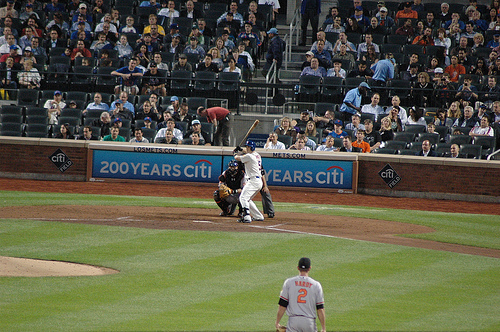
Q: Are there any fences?
A: No, there are no fences.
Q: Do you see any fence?
A: No, there are no fences.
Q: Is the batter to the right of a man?
A: No, the batter is to the left of a man.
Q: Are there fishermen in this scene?
A: No, there are no fishermen.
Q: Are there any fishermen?
A: No, there are no fishermen.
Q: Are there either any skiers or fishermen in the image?
A: No, there are no fishermen or skiers.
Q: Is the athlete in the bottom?
A: Yes, the athlete is in the bottom of the image.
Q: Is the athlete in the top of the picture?
A: No, the athlete is in the bottom of the image.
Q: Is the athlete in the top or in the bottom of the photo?
A: The athlete is in the bottom of the image.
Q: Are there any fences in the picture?
A: No, there are no fences.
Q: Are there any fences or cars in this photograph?
A: No, there are no fences or cars.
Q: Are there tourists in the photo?
A: No, there are no tourists.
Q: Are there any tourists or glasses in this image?
A: No, there are no tourists or glasses.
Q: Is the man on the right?
A: Yes, the man is on the right of the image.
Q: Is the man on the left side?
A: No, the man is on the right of the image.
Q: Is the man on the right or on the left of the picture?
A: The man is on the right of the image.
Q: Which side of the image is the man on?
A: The man is on the right of the image.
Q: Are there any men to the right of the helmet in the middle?
A: Yes, there is a man to the right of the helmet.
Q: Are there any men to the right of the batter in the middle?
A: Yes, there is a man to the right of the batter.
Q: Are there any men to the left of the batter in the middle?
A: No, the man is to the right of the batter.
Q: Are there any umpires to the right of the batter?
A: No, there is a man to the right of the batter.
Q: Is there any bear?
A: Yes, there is a bear.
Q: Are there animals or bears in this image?
A: Yes, there is a bear.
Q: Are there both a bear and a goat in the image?
A: No, there is a bear but no goats.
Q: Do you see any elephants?
A: No, there are no elephants.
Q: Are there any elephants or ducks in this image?
A: No, there are no elephants or ducks.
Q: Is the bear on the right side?
A: Yes, the bear is on the right of the image.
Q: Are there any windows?
A: Yes, there is a window.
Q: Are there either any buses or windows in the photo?
A: Yes, there is a window.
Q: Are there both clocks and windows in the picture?
A: No, there is a window but no clocks.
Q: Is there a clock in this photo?
A: No, there are no clocks.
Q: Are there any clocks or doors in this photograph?
A: No, there are no clocks or doors.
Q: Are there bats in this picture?
A: Yes, there is a bat.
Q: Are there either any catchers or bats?
A: Yes, there is a bat.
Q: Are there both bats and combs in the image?
A: No, there is a bat but no combs.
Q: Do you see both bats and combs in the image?
A: No, there is a bat but no combs.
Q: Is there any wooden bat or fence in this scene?
A: Yes, there is a wood bat.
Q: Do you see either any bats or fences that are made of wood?
A: Yes, the bat is made of wood.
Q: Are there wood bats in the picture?
A: Yes, there is a wood bat.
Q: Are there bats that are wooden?
A: Yes, there is a bat that is wooden.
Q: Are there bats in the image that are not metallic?
A: Yes, there is a wooden bat.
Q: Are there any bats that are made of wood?
A: Yes, there is a bat that is made of wood.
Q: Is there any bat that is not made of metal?
A: Yes, there is a bat that is made of wood.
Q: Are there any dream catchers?
A: No, there are no dream catchers.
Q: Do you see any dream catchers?
A: No, there are no dream catchers.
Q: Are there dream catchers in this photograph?
A: No, there are no dream catchers.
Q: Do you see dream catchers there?
A: No, there are no dream catchers.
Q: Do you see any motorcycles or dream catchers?
A: No, there are no dream catchers or motorcycles.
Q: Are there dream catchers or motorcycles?
A: No, there are no dream catchers or motorcycles.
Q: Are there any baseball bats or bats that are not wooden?
A: No, there is a bat but it is wooden.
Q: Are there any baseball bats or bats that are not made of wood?
A: No, there is a bat but it is made of wood.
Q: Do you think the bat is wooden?
A: Yes, the bat is wooden.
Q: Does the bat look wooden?
A: Yes, the bat is wooden.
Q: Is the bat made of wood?
A: Yes, the bat is made of wood.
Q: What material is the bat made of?
A: The bat is made of wood.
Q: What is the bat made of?
A: The bat is made of wood.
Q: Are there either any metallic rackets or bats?
A: No, there is a bat but it is wooden.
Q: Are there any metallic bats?
A: No, there is a bat but it is wooden.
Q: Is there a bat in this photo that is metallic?
A: No, there is a bat but it is wooden.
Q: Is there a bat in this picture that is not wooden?
A: No, there is a bat but it is wooden.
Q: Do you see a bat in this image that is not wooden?
A: No, there is a bat but it is wooden.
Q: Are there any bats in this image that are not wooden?
A: No, there is a bat but it is wooden.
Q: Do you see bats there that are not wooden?
A: No, there is a bat but it is wooden.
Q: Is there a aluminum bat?
A: No, there is a bat but it is made of wood.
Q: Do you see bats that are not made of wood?
A: No, there is a bat but it is made of wood.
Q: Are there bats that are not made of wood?
A: No, there is a bat but it is made of wood.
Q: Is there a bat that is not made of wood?
A: No, there is a bat but it is made of wood.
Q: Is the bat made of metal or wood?
A: The bat is made of wood.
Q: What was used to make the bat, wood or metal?
A: The bat is made of wood.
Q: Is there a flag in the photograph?
A: No, there are no flags.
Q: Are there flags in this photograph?
A: No, there are no flags.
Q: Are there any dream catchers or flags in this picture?
A: No, there are no flags or dream catchers.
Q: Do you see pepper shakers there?
A: No, there are no pepper shakers.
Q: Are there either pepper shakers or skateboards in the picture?
A: No, there are no pepper shakers or skateboards.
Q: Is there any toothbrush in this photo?
A: No, there are no toothbrushes.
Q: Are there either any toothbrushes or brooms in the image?
A: No, there are no toothbrushes or brooms.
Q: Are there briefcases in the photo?
A: No, there are no briefcases.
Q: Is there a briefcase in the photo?
A: No, there are no briefcases.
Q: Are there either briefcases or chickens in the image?
A: No, there are no briefcases or chickens.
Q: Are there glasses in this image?
A: No, there are no glasses.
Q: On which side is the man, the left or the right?
A: The man is on the right of the image.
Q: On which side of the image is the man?
A: The man is on the right of the image.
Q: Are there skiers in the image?
A: No, there are no skiers.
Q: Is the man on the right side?
A: Yes, the man is on the right of the image.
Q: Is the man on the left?
A: No, the man is on the right of the image.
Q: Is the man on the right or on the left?
A: The man is on the right of the image.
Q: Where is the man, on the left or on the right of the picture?
A: The man is on the right of the image.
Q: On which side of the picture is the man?
A: The man is on the right of the image.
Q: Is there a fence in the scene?
A: No, there are no fences.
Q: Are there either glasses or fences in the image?
A: No, there are no fences or glasses.